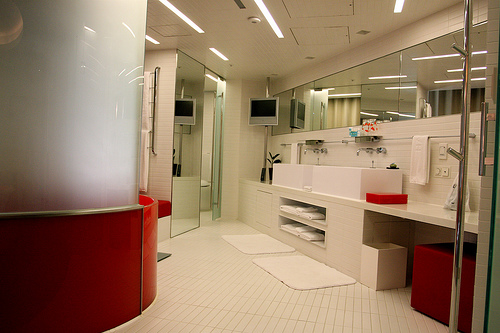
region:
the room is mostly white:
[25, 9, 494, 309]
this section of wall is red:
[12, 212, 132, 304]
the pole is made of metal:
[430, 7, 480, 325]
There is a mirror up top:
[255, 30, 477, 135]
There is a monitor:
[225, 83, 292, 130]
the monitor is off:
[244, 90, 291, 130]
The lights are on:
[102, 10, 329, 73]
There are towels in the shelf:
[272, 190, 334, 240]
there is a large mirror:
[176, 51, 203, 227]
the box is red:
[412, 240, 468, 320]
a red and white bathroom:
[10, 7, 494, 332]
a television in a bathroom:
[248, 88, 280, 133]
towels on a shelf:
[271, 191, 330, 248]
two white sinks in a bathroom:
[267, 138, 413, 202]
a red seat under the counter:
[409, 228, 499, 332]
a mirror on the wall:
[263, 17, 477, 137]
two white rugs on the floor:
[217, 221, 377, 299]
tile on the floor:
[184, 282, 376, 327]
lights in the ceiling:
[156, 3, 241, 69]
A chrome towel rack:
[445, 3, 480, 332]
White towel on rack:
[403, 129, 435, 188]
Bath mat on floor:
[219, 229, 299, 256]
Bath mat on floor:
[247, 251, 359, 296]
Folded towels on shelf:
[277, 196, 327, 245]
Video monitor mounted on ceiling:
[243, 74, 285, 131]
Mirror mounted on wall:
[267, 14, 487, 141]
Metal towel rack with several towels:
[141, 64, 168, 179]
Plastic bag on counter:
[439, 166, 472, 218]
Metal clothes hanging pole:
[436, 4, 478, 332]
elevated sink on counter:
[308, 161, 405, 203]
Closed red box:
[362, 191, 409, 205]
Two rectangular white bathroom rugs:
[222, 229, 356, 291]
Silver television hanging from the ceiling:
[245, 76, 280, 128]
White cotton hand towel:
[407, 135, 433, 185]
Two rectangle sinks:
[270, 160, 402, 199]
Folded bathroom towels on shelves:
[277, 194, 326, 248]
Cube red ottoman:
[410, 238, 479, 330]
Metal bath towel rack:
[141, 60, 162, 193]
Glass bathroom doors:
[170, 48, 226, 240]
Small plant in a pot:
[265, 151, 281, 181]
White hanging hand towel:
[403, 129, 433, 191]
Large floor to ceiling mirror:
[171, 45, 202, 240]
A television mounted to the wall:
[248, 93, 281, 133]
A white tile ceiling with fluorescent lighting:
[143, 0, 287, 47]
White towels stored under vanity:
[281, 199, 329, 248]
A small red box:
[367, 189, 409, 206]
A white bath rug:
[217, 233, 289, 256]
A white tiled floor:
[171, 288, 386, 330]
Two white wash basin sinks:
[268, 158, 405, 194]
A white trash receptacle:
[356, 241, 406, 292]